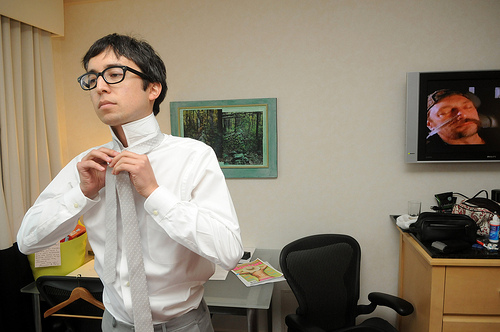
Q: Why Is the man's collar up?
A: To Put on a tie.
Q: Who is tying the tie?
A: The man.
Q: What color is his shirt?
A: White.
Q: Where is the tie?
A: Around the mans neck.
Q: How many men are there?
A: One.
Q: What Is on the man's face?
A: Glasses.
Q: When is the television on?
A: Now.